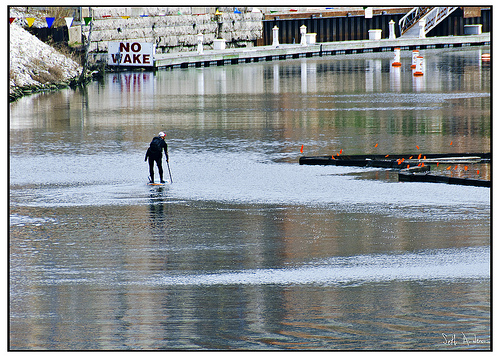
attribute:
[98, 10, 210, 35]
wall — thick stoned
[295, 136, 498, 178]
flags — orange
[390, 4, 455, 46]
ramp — leading down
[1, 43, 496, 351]
water — calm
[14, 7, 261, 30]
flags — different colored, hanging, over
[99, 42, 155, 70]
sign — white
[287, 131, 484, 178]
orange flags — small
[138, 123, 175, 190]
person — paddle boarding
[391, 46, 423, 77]
barrels — Orange, Six white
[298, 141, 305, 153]
buoy — orange, white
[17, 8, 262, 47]
flags —  many colors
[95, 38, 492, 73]
edging — black, white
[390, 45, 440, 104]
barrels — white, Orange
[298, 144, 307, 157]
flag — small, orange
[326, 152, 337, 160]
flag — orange, small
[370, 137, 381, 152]
flag — orange, small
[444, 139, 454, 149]
flag — orange, small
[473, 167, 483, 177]
flag — orange, small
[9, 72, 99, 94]
plants — green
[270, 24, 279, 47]
post — white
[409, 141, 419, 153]
flag — orange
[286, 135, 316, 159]
flag — orange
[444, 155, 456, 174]
flag — orange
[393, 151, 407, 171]
flag — orange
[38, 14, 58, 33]
flag — colored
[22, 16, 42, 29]
flag — colored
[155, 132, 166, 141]
hat — white